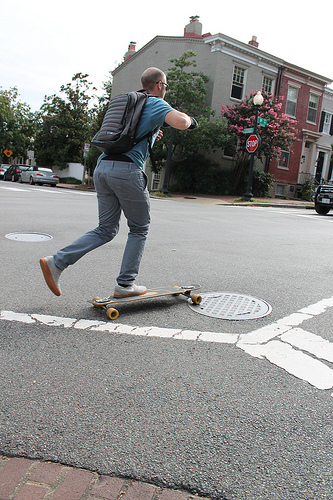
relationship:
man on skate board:
[38, 64, 205, 304] [89, 282, 210, 321]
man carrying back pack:
[38, 64, 205, 304] [90, 88, 145, 161]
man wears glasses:
[38, 64, 205, 304] [151, 78, 174, 92]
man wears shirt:
[38, 64, 205, 304] [96, 97, 177, 177]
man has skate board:
[38, 64, 205, 304] [89, 282, 210, 321]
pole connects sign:
[243, 150, 262, 202] [245, 134, 261, 156]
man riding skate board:
[38, 64, 205, 304] [89, 282, 210, 321]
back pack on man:
[90, 88, 145, 161] [38, 64, 205, 304]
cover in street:
[191, 289, 274, 325] [0, 181, 332, 496]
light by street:
[250, 89, 268, 110] [0, 181, 332, 496]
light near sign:
[250, 89, 268, 110] [245, 134, 261, 156]